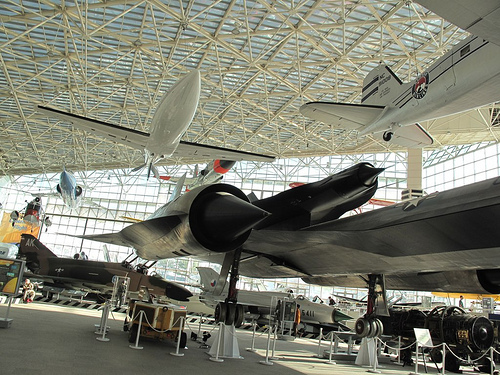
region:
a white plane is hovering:
[31, 24, 316, 338]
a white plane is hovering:
[60, 24, 255, 310]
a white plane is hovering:
[53, 51, 305, 291]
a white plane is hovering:
[30, 20, 245, 251]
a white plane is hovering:
[62, 49, 367, 359]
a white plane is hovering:
[47, 36, 264, 323]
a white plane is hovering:
[55, 70, 284, 334]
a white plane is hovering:
[68, 50, 229, 231]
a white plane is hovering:
[59, 64, 322, 321]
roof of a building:
[297, 47, 322, 85]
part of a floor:
[121, 352, 125, 353]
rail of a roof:
[325, 30, 341, 48]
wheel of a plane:
[361, 317, 378, 339]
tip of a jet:
[266, 197, 270, 223]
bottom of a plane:
[174, 85, 194, 129]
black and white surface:
[79, 293, 89, 308]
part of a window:
[441, 177, 446, 184]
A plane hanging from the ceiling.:
[293, 26, 499, 153]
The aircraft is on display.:
[18, 63, 285, 187]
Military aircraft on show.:
[15, 218, 196, 313]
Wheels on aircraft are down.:
[209, 291, 416, 346]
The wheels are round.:
[206, 298, 396, 357]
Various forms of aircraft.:
[6, 0, 498, 372]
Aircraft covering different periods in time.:
[2, 0, 499, 370]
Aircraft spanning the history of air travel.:
[2, 1, 499, 372]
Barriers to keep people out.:
[86, 272, 320, 369]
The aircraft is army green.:
[17, 232, 207, 315]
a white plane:
[79, 54, 285, 186]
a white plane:
[100, 27, 252, 259]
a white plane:
[82, 70, 169, 147]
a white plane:
[115, 91, 343, 345]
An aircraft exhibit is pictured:
[13, 8, 495, 363]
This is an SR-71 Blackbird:
[75, 165, 497, 295]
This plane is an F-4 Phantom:
[17, 229, 194, 306]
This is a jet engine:
[126, 182, 274, 271]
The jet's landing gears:
[209, 290, 393, 340]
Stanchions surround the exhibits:
[91, 294, 229, 365]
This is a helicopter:
[6, 187, 55, 229]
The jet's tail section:
[16, 229, 57, 276]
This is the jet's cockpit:
[119, 253, 166, 280]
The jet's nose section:
[163, 274, 198, 308]